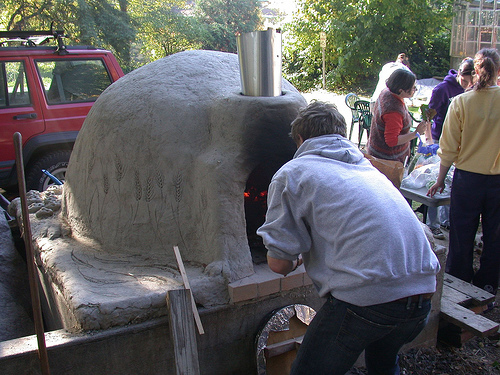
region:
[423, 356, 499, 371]
this is the ground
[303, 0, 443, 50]
this is a tree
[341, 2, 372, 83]
the tree is tall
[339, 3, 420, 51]
the leaves are green in color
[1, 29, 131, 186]
this is a car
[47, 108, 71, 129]
the car is red in color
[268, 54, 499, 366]
these are several people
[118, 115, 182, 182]
the stone is grey in color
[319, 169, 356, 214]
the hood is grey in color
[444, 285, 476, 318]
this is a bench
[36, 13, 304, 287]
a clay oven outdoors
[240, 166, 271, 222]
coals inside a clay oven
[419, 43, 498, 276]
woman wearing yellow sweater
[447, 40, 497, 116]
woman combing with a ponytail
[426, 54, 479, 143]
a lady wearing a purple top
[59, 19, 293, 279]
clay oven has an exhaust pipe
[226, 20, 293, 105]
Exhaust pipe is color silver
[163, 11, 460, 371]
a man is in front a clay oven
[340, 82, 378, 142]
green chair on the street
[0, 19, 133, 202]
a red car in front a clay oven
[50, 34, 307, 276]
large clay oven is grey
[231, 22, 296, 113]
metal tube on top of oven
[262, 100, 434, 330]
person wearing a grey hoodie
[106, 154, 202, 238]
the clay oven has wheat designs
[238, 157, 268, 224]
red glowing wood in the oven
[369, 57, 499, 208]
group of women at a table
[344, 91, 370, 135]
green plastics chairs in the background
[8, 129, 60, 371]
long brown wooden stick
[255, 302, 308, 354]
shiny silver paper covering an object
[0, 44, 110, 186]
red vehicle on the left side of oven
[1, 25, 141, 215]
red vehicle parked near a stove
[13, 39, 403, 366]
outdoor stove being used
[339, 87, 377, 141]
two green plastic chairs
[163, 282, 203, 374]
two by four leaning on the stove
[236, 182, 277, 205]
burning coals in the oven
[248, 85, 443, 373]
person using the oven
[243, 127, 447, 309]
grey colored hoodie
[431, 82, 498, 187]
woman's long sleeved yellow shirt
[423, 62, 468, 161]
girl's purple colored hoodie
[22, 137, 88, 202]
back tire of a red vehicle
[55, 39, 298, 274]
a wood burning oven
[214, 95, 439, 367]
man bending forward towards oven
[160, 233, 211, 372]
pieces of wood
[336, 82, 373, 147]
green plastic outdoor chairs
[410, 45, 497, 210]
woman touching top of a table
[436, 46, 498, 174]
woman dressed in a yellow sweater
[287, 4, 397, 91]
sign in front of foliage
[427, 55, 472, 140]
woman wearing a purple jacket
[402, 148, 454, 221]
packages on table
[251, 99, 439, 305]
man wearing a grey jacket